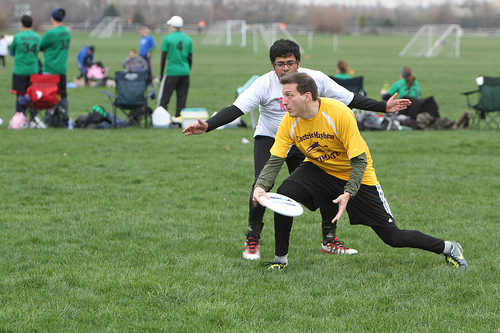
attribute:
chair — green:
[457, 71, 497, 131]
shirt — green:
[159, 29, 191, 79]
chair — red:
[19, 67, 66, 116]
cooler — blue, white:
[146, 104, 171, 129]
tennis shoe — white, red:
[237, 233, 269, 269]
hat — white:
[162, 11, 185, 31]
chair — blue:
[104, 67, 153, 125]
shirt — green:
[6, 27, 42, 77]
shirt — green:
[39, 25, 73, 72]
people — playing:
[177, 30, 482, 277]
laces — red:
[242, 235, 263, 254]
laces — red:
[327, 242, 347, 256]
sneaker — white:
[242, 234, 264, 261]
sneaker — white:
[316, 238, 356, 258]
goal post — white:
[393, 20, 433, 60]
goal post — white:
[456, 17, 463, 60]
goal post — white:
[425, 22, 458, 60]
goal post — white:
[423, 24, 435, 60]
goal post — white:
[222, 20, 237, 50]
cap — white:
[162, 13, 185, 26]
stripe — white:
[316, 106, 341, 141]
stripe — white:
[289, 118, 299, 141]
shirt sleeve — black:
[347, 93, 387, 112]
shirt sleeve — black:
[202, 104, 242, 131]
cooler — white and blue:
[149, 100, 169, 127]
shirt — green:
[160, 27, 198, 79]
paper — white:
[240, 129, 256, 148]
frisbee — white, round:
[254, 188, 303, 218]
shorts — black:
[278, 156, 398, 228]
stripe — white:
[374, 183, 394, 225]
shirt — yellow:
[270, 93, 377, 187]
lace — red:
[243, 232, 262, 255]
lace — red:
[322, 234, 344, 251]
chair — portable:
[105, 55, 156, 128]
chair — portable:
[17, 69, 67, 123]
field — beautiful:
[0, 22, 499, 327]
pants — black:
[272, 160, 450, 255]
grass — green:
[0, 27, 500, 329]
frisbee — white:
[257, 190, 303, 218]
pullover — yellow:
[268, 95, 379, 187]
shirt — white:
[227, 63, 357, 141]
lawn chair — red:
[14, 70, 69, 128]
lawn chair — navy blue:
[110, 70, 150, 129]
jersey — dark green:
[41, 26, 69, 76]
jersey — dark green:
[6, 31, 36, 78]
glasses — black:
[276, 59, 300, 68]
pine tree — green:
[130, 10, 146, 29]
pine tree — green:
[101, 1, 121, 16]